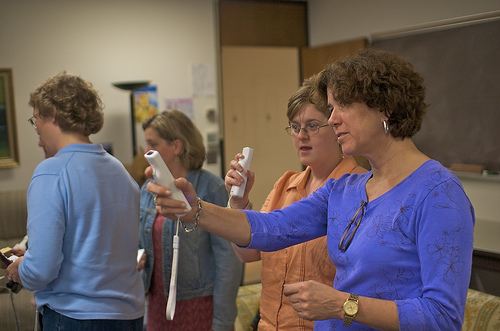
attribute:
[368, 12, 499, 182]
blackboard — empty, in background, rectangular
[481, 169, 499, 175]
eraser — for blackboard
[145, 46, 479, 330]
woman — causasian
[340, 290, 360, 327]
watch — gold, round faced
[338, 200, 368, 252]
glasses — dark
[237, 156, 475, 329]
shirt — purple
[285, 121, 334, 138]
glasses — thin wire frames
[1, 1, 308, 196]
wall — white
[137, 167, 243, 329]
jacket — jean jacket, denim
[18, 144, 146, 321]
shirt — blue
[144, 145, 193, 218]
wii remote — white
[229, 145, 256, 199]
wii remote — white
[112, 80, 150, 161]
floor lamp — black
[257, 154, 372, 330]
shirt — orange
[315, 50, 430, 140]
hair — short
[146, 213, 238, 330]
dress — red, white